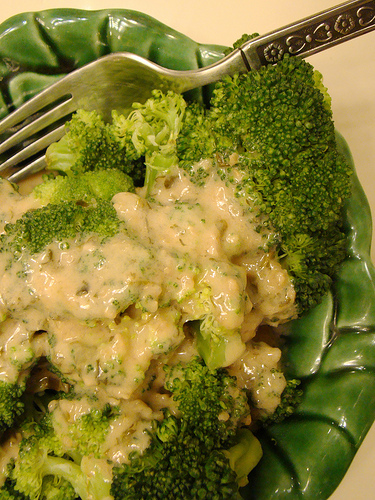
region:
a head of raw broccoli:
[239, 56, 342, 262]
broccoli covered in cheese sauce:
[16, 215, 283, 453]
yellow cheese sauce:
[51, 273, 74, 296]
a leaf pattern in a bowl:
[311, 303, 372, 458]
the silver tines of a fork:
[1, 88, 77, 172]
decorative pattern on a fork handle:
[259, 8, 374, 60]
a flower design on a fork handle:
[259, 42, 282, 62]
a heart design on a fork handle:
[310, 23, 331, 42]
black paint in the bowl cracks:
[6, 60, 84, 78]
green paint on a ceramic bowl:
[299, 433, 330, 479]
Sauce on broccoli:
[32, 195, 308, 380]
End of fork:
[19, 60, 181, 165]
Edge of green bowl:
[310, 304, 357, 481]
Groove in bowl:
[37, 19, 69, 65]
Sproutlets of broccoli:
[166, 435, 216, 482]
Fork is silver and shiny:
[91, 58, 200, 106]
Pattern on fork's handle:
[266, 6, 373, 66]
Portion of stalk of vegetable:
[44, 453, 80, 482]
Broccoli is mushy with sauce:
[34, 169, 237, 376]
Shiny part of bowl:
[335, 409, 351, 432]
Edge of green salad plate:
[316, 289, 367, 493]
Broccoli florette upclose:
[162, 427, 210, 497]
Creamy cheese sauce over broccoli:
[74, 272, 178, 341]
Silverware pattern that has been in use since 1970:
[234, 8, 371, 88]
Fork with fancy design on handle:
[3, 6, 373, 160]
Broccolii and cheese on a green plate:
[55, 309, 354, 497]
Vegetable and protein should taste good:
[7, 373, 142, 498]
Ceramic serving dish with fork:
[4, 17, 186, 171]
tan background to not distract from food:
[195, 6, 272, 32]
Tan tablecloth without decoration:
[157, 4, 292, 23]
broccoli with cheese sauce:
[33, 174, 282, 477]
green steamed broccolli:
[249, 103, 317, 190]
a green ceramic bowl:
[21, 5, 136, 78]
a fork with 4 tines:
[13, 30, 244, 210]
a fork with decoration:
[254, 2, 358, 70]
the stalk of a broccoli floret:
[39, 446, 79, 478]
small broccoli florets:
[283, 150, 328, 213]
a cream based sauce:
[109, 233, 183, 328]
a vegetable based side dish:
[13, 18, 372, 423]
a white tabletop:
[200, 10, 241, 36]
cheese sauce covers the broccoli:
[148, 174, 243, 295]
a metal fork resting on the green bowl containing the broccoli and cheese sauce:
[6, 41, 171, 182]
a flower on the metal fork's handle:
[303, 315, 371, 495]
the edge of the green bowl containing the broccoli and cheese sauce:
[299, 369, 371, 499]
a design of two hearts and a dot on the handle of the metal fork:
[283, 18, 332, 54]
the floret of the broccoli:
[245, 77, 316, 146]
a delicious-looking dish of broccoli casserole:
[7, 10, 335, 375]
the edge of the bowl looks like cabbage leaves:
[3, 5, 190, 60]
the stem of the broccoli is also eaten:
[45, 445, 135, 494]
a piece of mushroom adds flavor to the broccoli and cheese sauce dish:
[26, 350, 73, 405]